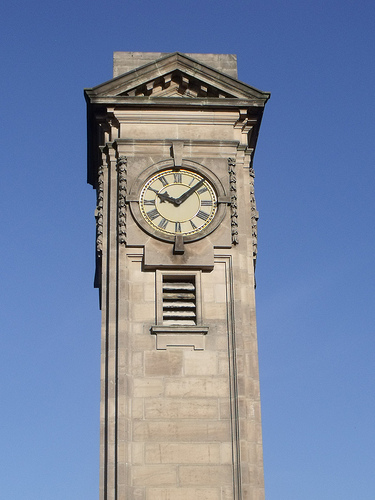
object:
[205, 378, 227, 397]
stone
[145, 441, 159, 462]
stone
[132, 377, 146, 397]
stone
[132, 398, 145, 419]
stone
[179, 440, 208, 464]
stone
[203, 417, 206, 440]
line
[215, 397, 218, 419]
line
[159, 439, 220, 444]
line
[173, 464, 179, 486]
line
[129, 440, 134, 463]
line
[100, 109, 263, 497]
wall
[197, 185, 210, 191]
two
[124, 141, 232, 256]
four keystones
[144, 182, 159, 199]
roman numeral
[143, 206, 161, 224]
roman numeral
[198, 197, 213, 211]
roman numeral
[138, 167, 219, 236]
clock face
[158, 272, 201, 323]
shutters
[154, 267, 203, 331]
window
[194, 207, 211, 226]
number 4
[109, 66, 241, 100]
triangles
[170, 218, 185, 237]
numeral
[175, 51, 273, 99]
edging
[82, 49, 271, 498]
brickwork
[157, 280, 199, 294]
slats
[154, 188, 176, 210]
hour hand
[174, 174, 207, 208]
minute hand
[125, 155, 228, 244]
clock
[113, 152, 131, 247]
stone decoration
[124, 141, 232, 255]
face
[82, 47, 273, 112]
roof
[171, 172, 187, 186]
numeral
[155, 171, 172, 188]
numeral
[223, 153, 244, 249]
decoration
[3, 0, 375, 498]
sky